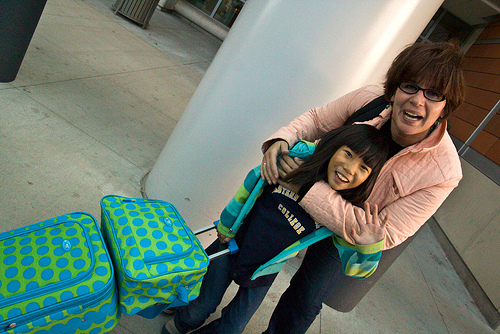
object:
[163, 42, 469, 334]
woman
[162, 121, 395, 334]
girl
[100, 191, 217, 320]
bag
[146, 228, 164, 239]
dots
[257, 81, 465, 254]
jacket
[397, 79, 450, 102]
eyeglasses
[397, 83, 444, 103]
frame